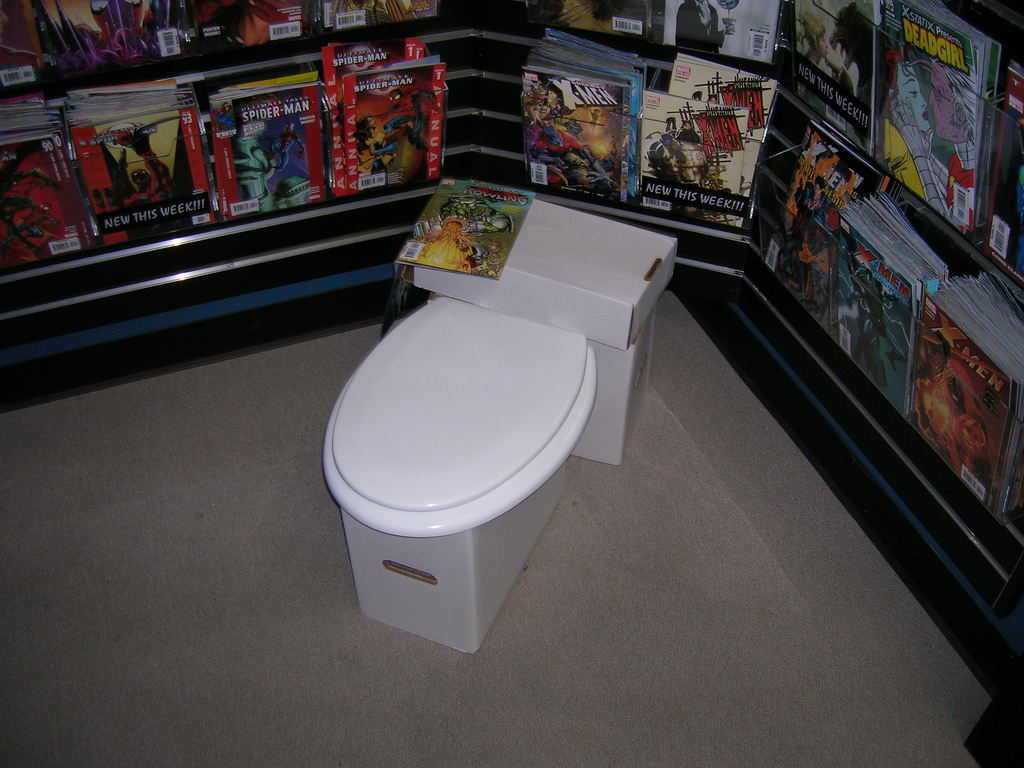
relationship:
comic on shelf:
[511, 73, 633, 197] [7, 66, 1022, 569]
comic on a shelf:
[340, 66, 457, 187] [14, 59, 492, 253]